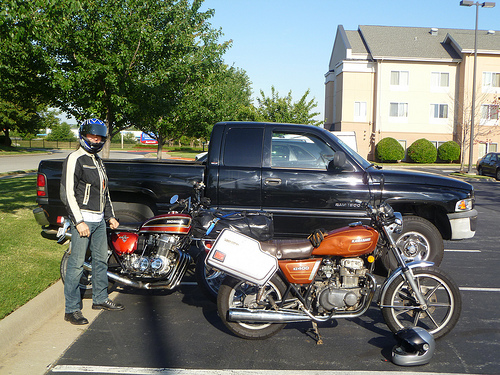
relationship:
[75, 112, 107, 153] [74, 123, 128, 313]
helmet on man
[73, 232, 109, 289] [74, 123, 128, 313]
jeans on man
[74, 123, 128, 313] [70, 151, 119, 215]
man wearing jacket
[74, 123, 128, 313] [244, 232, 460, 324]
man beside bike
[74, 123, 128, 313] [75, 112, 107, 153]
man wearing helmet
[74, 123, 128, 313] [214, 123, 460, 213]
man near truck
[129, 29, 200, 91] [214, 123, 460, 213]
tree behind truck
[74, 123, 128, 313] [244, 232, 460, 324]
man near bike